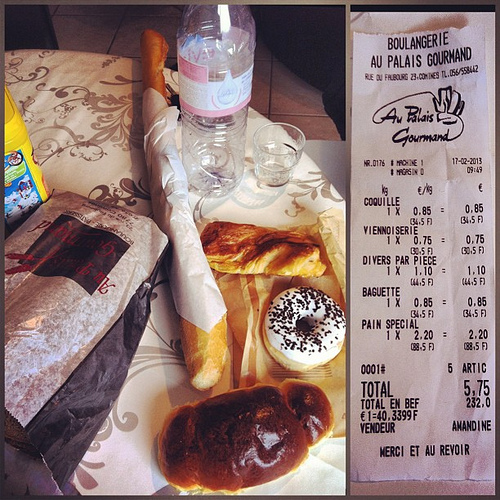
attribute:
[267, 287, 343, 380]
donut — white, iced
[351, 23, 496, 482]
receipt —  in French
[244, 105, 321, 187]
glass —  empty, for water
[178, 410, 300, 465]
top — dark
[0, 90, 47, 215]
yellow container — plastic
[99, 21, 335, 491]
pastries — collection,  from shop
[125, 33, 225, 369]
bread — loaf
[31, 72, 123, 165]
tablecloth — brown, white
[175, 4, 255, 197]
bottle — plastic, empty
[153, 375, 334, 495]
bread — glossy, brown, baked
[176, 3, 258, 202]
water bottle — empty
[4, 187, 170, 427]
bag —  empty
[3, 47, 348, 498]
table — round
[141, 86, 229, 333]
paper — white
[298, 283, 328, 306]
sprinkles — chocolate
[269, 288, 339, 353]
sprinkles — chocolate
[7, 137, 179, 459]
bag — paper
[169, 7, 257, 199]
bottle — plastic, big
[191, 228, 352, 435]
bag — paper